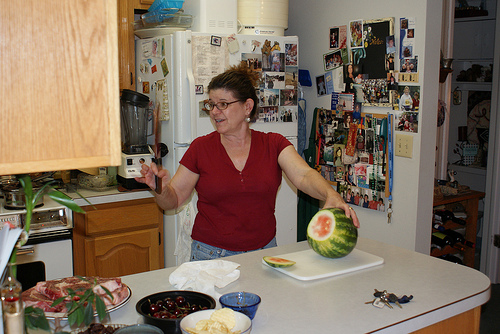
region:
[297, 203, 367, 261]
watermelon with end cut off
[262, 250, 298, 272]
cut rind of watermelon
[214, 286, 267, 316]
bowl on the countertop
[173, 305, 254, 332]
bowl on the countertop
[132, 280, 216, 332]
bowl on the countertop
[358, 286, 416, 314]
group of keys on the countertop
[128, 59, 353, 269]
lady wearing red shirt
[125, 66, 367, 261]
lady wearing some glasses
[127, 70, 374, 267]
lady holding a watermelon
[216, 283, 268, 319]
blue bowl made of glass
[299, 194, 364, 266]
Freshly cut watermelon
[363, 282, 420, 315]
key ring laying on counter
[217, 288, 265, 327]
blue glass bowl on counter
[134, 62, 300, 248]
Woman with large knife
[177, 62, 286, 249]
Woman wearing maroon shirt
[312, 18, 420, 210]
large collection of family pictures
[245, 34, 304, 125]
refrigerator used as bulletin board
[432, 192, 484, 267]
wine stored in wood rack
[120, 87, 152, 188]
Blender sitting on counter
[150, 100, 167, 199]
large knife with black handle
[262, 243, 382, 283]
a plastic cutting board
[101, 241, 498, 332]
a large white counter top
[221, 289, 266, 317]
a small blue bowl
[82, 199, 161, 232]
a brown drawer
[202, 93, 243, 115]
a woman's eyeglasses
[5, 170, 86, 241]
part of a green leaf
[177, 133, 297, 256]
a woman's short sleeve shirt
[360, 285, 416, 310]
a set of keys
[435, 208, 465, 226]
a large wine bottle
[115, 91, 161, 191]
a large black and white blender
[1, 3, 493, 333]
woman preparing food in a kitchen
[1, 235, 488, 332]
large counter-top with rounded edges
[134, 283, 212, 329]
dark cherries in a black container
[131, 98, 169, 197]
woman holding a large knife with two fingers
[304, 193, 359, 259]
woman's hand resting on a watermelon that is missing a piece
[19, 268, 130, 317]
large slices of raw meat on a plate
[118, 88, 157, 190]
a blender with the lid askew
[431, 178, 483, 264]
wine bottles in a wine rack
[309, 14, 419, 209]
multitude of photographs on wall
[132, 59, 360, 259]
Woman in the kitchen holds a watermelon and knife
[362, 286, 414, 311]
Set of keys sit on the counter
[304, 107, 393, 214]
Bulletin board filled with pictures on the wall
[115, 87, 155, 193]
Empty blender sits on the counter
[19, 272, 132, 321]
Raw meat on a plate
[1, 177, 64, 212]
Silver pan on the stove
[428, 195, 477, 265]
Wine bottles sit in wine rack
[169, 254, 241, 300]
Crumpled paper napkin on counter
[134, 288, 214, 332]
Black bowl full of cherries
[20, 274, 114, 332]
Plant on the counter